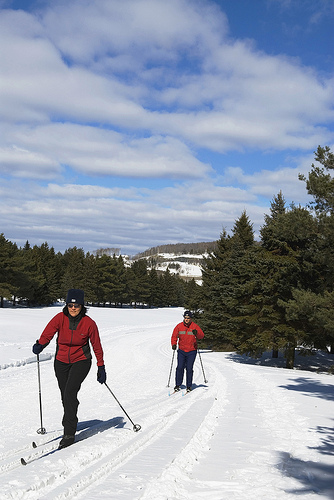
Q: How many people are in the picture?
A: 2.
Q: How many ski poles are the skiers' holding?
A: 4.